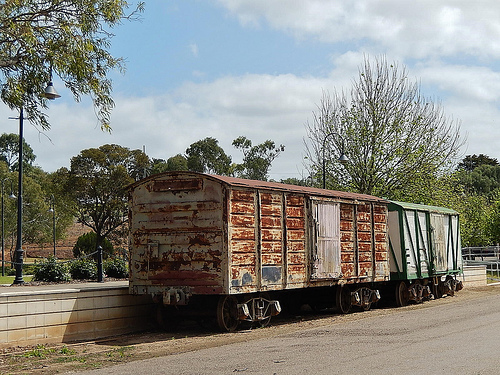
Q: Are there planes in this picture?
A: No, there are no planes.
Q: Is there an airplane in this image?
A: No, there are no airplanes.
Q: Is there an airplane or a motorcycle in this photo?
A: No, there are no airplanes or motorcycles.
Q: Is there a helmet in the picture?
A: No, there are no helmets.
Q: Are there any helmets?
A: No, there are no helmets.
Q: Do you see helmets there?
A: No, there are no helmets.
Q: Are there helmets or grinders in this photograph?
A: No, there are no helmets or grinders.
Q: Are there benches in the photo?
A: No, there are no benches.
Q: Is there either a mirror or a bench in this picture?
A: No, there are no benches or mirrors.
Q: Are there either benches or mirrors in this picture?
A: No, there are no benches or mirrors.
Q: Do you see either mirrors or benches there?
A: No, there are no benches or mirrors.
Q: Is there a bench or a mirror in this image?
A: No, there are no benches or mirrors.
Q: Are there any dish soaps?
A: No, there are no dish soaps.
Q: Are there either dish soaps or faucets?
A: No, there are no dish soaps or faucets.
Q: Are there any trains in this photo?
A: Yes, there is a train.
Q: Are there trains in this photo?
A: Yes, there is a train.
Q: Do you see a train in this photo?
A: Yes, there is a train.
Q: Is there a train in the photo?
A: Yes, there is a train.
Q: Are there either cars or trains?
A: Yes, there is a train.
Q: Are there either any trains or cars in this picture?
A: Yes, there is a train.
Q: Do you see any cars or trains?
A: Yes, there is a train.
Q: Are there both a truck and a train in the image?
A: No, there is a train but no trucks.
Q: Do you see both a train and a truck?
A: No, there is a train but no trucks.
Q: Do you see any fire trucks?
A: No, there are no fire trucks.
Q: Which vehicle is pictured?
A: The vehicle is a train.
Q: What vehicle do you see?
A: The vehicle is a train.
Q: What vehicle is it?
A: The vehicle is a train.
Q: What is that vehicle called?
A: This is a train.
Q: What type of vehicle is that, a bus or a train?
A: This is a train.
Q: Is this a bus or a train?
A: This is a train.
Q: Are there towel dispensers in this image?
A: No, there are no towel dispensers.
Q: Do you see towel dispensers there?
A: No, there are no towel dispensers.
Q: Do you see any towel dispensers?
A: No, there are no towel dispensers.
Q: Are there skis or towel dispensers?
A: No, there are no towel dispensers or skis.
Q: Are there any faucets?
A: No, there are no faucets.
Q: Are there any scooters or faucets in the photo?
A: No, there are no faucets or scooters.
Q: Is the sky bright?
A: Yes, the sky is bright.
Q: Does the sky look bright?
A: Yes, the sky is bright.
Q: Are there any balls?
A: No, there are no balls.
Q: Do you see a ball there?
A: No, there are no balls.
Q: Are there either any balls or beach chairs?
A: No, there are no balls or beach chairs.